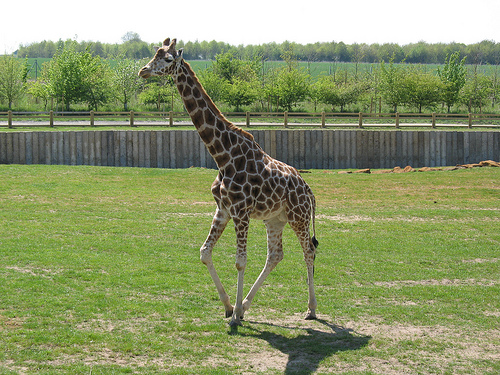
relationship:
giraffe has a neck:
[135, 36, 320, 328] [172, 59, 236, 174]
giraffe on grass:
[135, 36, 320, 328] [0, 161, 499, 374]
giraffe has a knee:
[135, 36, 320, 328] [198, 245, 214, 267]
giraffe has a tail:
[135, 36, 320, 328] [306, 185, 319, 250]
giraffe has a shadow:
[135, 36, 320, 328] [226, 303, 375, 375]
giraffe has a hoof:
[135, 36, 320, 328] [301, 307, 318, 322]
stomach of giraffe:
[254, 199, 288, 224] [135, 36, 320, 328]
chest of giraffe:
[238, 182, 274, 222] [135, 36, 320, 328]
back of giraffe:
[241, 130, 304, 188] [135, 36, 320, 328]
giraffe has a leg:
[135, 36, 320, 328] [292, 221, 318, 322]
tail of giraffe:
[306, 185, 319, 250] [135, 36, 320, 328]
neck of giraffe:
[172, 59, 236, 174] [135, 36, 320, 328]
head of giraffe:
[137, 36, 185, 81] [135, 36, 320, 328]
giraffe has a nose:
[135, 36, 320, 328] [136, 66, 151, 74]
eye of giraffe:
[164, 54, 177, 64] [135, 36, 320, 328]